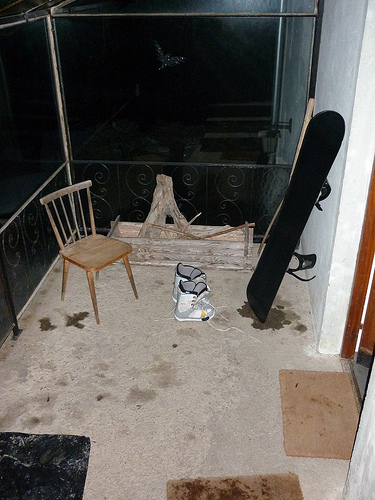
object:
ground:
[97, 350, 267, 462]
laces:
[196, 296, 262, 344]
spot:
[234, 301, 288, 331]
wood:
[103, 173, 251, 268]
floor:
[0, 240, 350, 498]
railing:
[0, 158, 295, 352]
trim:
[321, 228, 374, 382]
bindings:
[285, 249, 317, 281]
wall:
[288, 0, 373, 357]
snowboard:
[243, 108, 346, 326]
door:
[338, 130, 373, 419]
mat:
[278, 368, 363, 458]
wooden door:
[338, 157, 373, 359]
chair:
[38, 180, 139, 326]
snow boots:
[170, 262, 207, 304]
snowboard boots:
[169, 278, 217, 325]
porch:
[0, 1, 364, 498]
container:
[105, 216, 258, 273]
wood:
[136, 170, 192, 240]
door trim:
[334, 157, 374, 360]